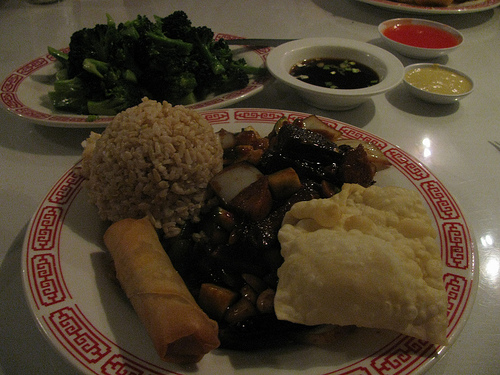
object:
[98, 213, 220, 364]
roll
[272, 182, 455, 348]
wonton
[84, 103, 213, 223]
rice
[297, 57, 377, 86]
sauce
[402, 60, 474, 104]
sauce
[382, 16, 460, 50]
sauce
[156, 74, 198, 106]
broccoli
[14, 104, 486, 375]
plate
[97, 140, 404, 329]
food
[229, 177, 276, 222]
meat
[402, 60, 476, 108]
bowl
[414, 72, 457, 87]
mustard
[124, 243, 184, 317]
egg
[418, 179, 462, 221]
pattern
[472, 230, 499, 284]
light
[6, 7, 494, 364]
table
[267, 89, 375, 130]
shadow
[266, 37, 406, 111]
bowl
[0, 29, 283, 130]
plate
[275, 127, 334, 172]
rib